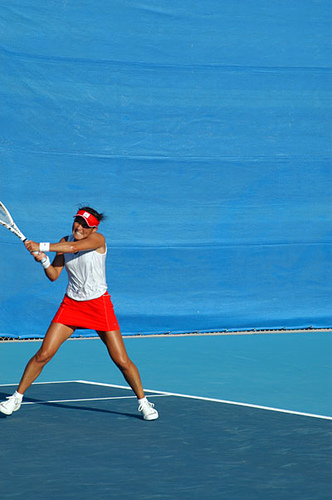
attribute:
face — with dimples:
[70, 215, 90, 239]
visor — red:
[69, 203, 99, 228]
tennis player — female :
[3, 190, 133, 425]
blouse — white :
[64, 234, 108, 301]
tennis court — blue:
[0, 371, 331, 497]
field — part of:
[0, 326, 328, 498]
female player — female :
[1, 202, 160, 422]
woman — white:
[4, 205, 164, 429]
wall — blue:
[2, 2, 331, 333]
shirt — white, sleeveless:
[55, 232, 105, 295]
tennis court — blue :
[3, 330, 330, 498]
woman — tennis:
[21, 195, 153, 447]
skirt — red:
[49, 292, 121, 334]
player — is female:
[22, 195, 120, 357]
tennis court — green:
[3, 358, 330, 499]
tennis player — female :
[19, 196, 148, 305]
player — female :
[0, 202, 160, 421]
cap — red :
[72, 209, 99, 229]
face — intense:
[72, 218, 91, 240]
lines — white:
[70, 377, 329, 426]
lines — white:
[0, 377, 80, 390]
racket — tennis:
[0, 199, 38, 256]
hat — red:
[70, 207, 98, 229]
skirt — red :
[46, 295, 123, 334]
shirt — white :
[58, 236, 112, 308]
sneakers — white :
[1, 390, 162, 422]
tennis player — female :
[10, 207, 161, 417]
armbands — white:
[35, 238, 55, 269]